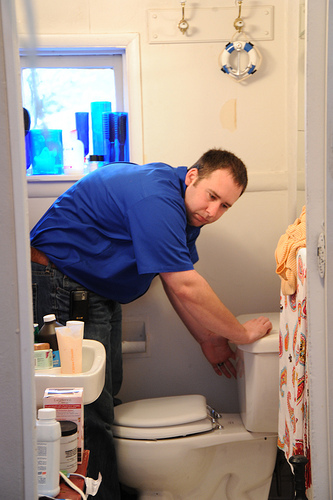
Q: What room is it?
A: It is a bathroom.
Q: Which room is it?
A: It is a bathroom.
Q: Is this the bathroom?
A: Yes, it is the bathroom.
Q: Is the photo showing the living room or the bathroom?
A: It is showing the bathroom.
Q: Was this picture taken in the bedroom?
A: No, the picture was taken in the bathroom.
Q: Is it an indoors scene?
A: Yes, it is indoors.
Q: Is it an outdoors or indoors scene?
A: It is indoors.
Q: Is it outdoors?
A: No, it is indoors.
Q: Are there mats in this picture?
A: No, there are no mats.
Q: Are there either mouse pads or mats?
A: No, there are no mats or mouse pads.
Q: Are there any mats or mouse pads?
A: No, there are no mats or mouse pads.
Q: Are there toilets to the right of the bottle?
A: Yes, there is a toilet to the right of the bottle.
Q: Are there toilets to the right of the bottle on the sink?
A: Yes, there is a toilet to the right of the bottle.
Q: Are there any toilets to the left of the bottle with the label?
A: No, the toilet is to the right of the bottle.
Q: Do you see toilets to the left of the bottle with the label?
A: No, the toilet is to the right of the bottle.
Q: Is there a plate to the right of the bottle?
A: No, there is a toilet to the right of the bottle.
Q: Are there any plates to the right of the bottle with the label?
A: No, there is a toilet to the right of the bottle.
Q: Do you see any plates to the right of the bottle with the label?
A: No, there is a toilet to the right of the bottle.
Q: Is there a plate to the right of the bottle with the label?
A: No, there is a toilet to the right of the bottle.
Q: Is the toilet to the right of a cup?
A: No, the toilet is to the right of a bottle.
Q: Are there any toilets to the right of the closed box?
A: Yes, there is a toilet to the right of the box.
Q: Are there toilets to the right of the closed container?
A: Yes, there is a toilet to the right of the box.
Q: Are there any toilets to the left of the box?
A: No, the toilet is to the right of the box.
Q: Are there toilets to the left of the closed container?
A: No, the toilet is to the right of the box.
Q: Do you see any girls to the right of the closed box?
A: No, there is a toilet to the right of the box.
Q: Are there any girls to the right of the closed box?
A: No, there is a toilet to the right of the box.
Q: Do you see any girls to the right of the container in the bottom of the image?
A: No, there is a toilet to the right of the box.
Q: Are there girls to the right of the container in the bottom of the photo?
A: No, there is a toilet to the right of the box.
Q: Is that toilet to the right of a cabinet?
A: No, the toilet is to the right of a box.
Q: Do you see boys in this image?
A: No, there are no boys.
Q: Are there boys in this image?
A: No, there are no boys.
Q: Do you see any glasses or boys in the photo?
A: No, there are no boys or glasses.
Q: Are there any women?
A: No, there are no women.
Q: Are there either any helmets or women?
A: No, there are no women or helmets.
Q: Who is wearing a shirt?
A: The man is wearing a shirt.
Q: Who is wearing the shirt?
A: The man is wearing a shirt.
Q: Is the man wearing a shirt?
A: Yes, the man is wearing a shirt.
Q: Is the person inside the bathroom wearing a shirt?
A: Yes, the man is wearing a shirt.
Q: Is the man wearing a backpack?
A: No, the man is wearing a shirt.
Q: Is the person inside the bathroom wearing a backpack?
A: No, the man is wearing a shirt.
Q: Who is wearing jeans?
A: The man is wearing jeans.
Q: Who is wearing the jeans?
A: The man is wearing jeans.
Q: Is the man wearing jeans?
A: Yes, the man is wearing jeans.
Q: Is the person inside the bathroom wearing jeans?
A: Yes, the man is wearing jeans.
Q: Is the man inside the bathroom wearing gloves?
A: No, the man is wearing jeans.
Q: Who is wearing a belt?
A: The man is wearing a belt.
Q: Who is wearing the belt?
A: The man is wearing a belt.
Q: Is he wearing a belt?
A: Yes, the man is wearing a belt.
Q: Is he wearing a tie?
A: No, the man is wearing a belt.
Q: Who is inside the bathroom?
A: The man is inside the bathroom.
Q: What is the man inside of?
A: The man is inside the bathroom.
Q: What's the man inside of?
A: The man is inside the bathroom.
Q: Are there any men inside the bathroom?
A: Yes, there is a man inside the bathroom.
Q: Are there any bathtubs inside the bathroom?
A: No, there is a man inside the bathroom.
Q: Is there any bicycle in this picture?
A: No, there are no bicycles.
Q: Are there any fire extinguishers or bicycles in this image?
A: No, there are no bicycles or fire extinguishers.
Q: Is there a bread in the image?
A: No, there is no breads.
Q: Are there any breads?
A: No, there are no breads.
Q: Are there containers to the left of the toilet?
A: Yes, there is a container to the left of the toilet.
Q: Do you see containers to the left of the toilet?
A: Yes, there is a container to the left of the toilet.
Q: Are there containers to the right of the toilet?
A: No, the container is to the left of the toilet.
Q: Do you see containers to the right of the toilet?
A: No, the container is to the left of the toilet.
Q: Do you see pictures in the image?
A: No, there are no pictures.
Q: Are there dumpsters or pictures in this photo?
A: No, there are no pictures or dumpsters.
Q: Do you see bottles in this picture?
A: Yes, there is a bottle.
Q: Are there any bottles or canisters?
A: Yes, there is a bottle.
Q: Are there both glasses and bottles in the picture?
A: No, there is a bottle but no glasses.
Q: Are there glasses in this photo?
A: No, there are no glasses.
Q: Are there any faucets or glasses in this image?
A: No, there are no glasses or faucets.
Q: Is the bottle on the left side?
A: Yes, the bottle is on the left of the image.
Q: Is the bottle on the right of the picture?
A: No, the bottle is on the left of the image.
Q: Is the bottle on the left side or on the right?
A: The bottle is on the left of the image.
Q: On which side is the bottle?
A: The bottle is on the left of the image.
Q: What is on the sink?
A: The bottle is on the sink.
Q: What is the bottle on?
A: The bottle is on the sink.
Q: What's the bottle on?
A: The bottle is on the sink.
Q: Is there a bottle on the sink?
A: Yes, there is a bottle on the sink.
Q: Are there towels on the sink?
A: No, there is a bottle on the sink.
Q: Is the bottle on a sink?
A: Yes, the bottle is on a sink.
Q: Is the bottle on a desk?
A: No, the bottle is on a sink.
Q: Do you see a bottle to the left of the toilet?
A: Yes, there is a bottle to the left of the toilet.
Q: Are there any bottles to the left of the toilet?
A: Yes, there is a bottle to the left of the toilet.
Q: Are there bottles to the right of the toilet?
A: No, the bottle is to the left of the toilet.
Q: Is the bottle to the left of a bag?
A: No, the bottle is to the left of the toilet.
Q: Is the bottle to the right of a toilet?
A: No, the bottle is to the left of a toilet.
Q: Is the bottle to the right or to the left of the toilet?
A: The bottle is to the left of the toilet.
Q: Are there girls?
A: No, there are no girls.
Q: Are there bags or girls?
A: No, there are no girls or bags.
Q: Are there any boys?
A: No, there are no boys.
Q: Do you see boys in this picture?
A: No, there are no boys.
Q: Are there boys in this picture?
A: No, there are no boys.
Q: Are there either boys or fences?
A: No, there are no boys or fences.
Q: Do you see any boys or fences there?
A: No, there are no boys or fences.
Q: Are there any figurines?
A: No, there are no figurines.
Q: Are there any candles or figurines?
A: No, there are no figurines or candles.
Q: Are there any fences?
A: No, there are no fences.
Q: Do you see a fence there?
A: No, there are no fences.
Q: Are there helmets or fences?
A: No, there are no fences or helmets.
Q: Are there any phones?
A: Yes, there is a phone.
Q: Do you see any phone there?
A: Yes, there is a phone.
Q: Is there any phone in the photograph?
A: Yes, there is a phone.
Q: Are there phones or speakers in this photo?
A: Yes, there is a phone.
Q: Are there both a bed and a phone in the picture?
A: No, there is a phone but no beds.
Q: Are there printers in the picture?
A: No, there are no printers.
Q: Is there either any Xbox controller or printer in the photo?
A: No, there are no printers or Xbox controllers.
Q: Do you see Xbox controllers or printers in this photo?
A: No, there are no printers or Xbox controllers.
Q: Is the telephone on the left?
A: Yes, the telephone is on the left of the image.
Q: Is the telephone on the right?
A: No, the telephone is on the left of the image.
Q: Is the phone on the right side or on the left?
A: The phone is on the left of the image.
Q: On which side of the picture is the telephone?
A: The telephone is on the left of the image.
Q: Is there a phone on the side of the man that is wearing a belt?
A: Yes, there is a phone on the side of the man.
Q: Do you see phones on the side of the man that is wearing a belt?
A: Yes, there is a phone on the side of the man.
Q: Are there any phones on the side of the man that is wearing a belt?
A: Yes, there is a phone on the side of the man.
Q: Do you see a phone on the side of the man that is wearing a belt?
A: Yes, there is a phone on the side of the man.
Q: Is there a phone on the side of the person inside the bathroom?
A: Yes, there is a phone on the side of the man.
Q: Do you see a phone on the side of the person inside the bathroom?
A: Yes, there is a phone on the side of the man.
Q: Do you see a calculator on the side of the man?
A: No, there is a phone on the side of the man.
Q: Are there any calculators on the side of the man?
A: No, there is a phone on the side of the man.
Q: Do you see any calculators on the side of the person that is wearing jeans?
A: No, there is a phone on the side of the man.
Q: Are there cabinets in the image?
A: No, there are no cabinets.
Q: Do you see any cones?
A: No, there are no cones.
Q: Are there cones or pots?
A: No, there are no cones or pots.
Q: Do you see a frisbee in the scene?
A: No, there are no frisbees.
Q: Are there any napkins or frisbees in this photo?
A: No, there are no frisbees or napkins.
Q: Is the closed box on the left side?
A: Yes, the box is on the left of the image.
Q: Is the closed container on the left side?
A: Yes, the box is on the left of the image.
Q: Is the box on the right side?
A: No, the box is on the left of the image.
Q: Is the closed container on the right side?
A: No, the box is on the left of the image.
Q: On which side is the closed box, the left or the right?
A: The box is on the left of the image.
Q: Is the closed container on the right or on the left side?
A: The box is on the left of the image.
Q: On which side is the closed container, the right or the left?
A: The box is on the left of the image.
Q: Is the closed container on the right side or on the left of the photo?
A: The box is on the left of the image.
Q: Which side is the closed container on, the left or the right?
A: The box is on the left of the image.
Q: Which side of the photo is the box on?
A: The box is on the left of the image.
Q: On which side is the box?
A: The box is on the left of the image.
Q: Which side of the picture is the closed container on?
A: The box is on the left of the image.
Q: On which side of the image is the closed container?
A: The box is on the left of the image.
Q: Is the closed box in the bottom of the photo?
A: Yes, the box is in the bottom of the image.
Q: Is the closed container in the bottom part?
A: Yes, the box is in the bottom of the image.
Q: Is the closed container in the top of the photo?
A: No, the box is in the bottom of the image.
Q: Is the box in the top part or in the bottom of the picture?
A: The box is in the bottom of the image.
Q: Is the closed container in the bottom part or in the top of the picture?
A: The box is in the bottom of the image.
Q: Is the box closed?
A: Yes, the box is closed.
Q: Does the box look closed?
A: Yes, the box is closed.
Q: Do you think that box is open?
A: No, the box is closed.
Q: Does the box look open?
A: No, the box is closed.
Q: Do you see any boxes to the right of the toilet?
A: No, the box is to the left of the toilet.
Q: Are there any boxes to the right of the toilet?
A: No, the box is to the left of the toilet.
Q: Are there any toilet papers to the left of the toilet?
A: No, there is a box to the left of the toilet.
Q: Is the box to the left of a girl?
A: No, the box is to the left of the toilet.